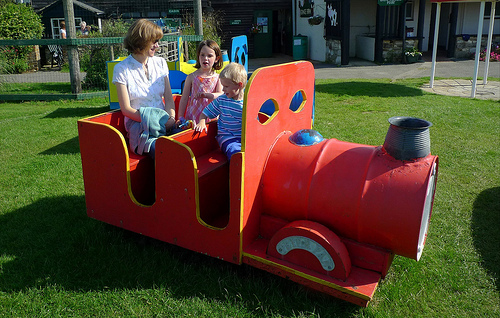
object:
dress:
[185, 71, 220, 122]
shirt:
[201, 94, 259, 155]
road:
[0, 61, 465, 83]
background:
[0, 0, 500, 318]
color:
[295, 267, 340, 281]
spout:
[382, 116, 433, 162]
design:
[257, 88, 308, 126]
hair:
[122, 18, 163, 56]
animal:
[326, 5, 338, 27]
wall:
[297, 2, 327, 56]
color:
[354, 60, 420, 77]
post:
[63, 0, 81, 94]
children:
[175, 39, 224, 127]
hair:
[192, 39, 224, 70]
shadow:
[0, 195, 358, 318]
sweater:
[125, 106, 170, 155]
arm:
[114, 69, 141, 123]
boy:
[193, 61, 258, 159]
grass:
[0, 130, 34, 192]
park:
[0, 0, 500, 318]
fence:
[0, 33, 178, 102]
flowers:
[470, 44, 500, 62]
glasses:
[149, 39, 159, 44]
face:
[148, 38, 160, 58]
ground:
[5, 177, 483, 316]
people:
[111, 17, 185, 157]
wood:
[241, 58, 316, 199]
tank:
[262, 129, 438, 262]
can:
[291, 32, 310, 61]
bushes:
[0, 0, 46, 75]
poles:
[427, 2, 441, 87]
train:
[76, 60, 440, 307]